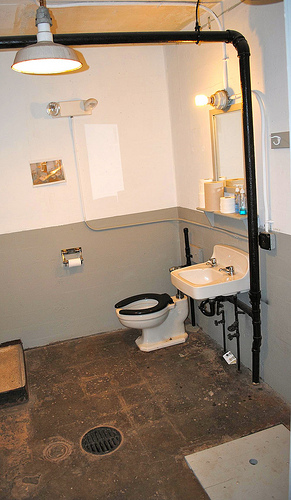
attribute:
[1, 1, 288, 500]
bathroom — incomplete, broken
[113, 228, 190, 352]
toilet — commercial, black, white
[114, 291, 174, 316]
seat — black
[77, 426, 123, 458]
drain — metal, circular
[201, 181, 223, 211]
paper towels — brown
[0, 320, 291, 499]
floor — cement, tileless, dirty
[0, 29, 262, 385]
piping — black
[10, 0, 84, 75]
lamp — hanging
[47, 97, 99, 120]
lights — off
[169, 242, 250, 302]
sink — white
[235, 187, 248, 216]
soap dispenser — empty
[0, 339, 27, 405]
litter box — black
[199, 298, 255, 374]
pipes — black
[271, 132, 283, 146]
hook — white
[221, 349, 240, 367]
paper — white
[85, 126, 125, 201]
paint mark — white